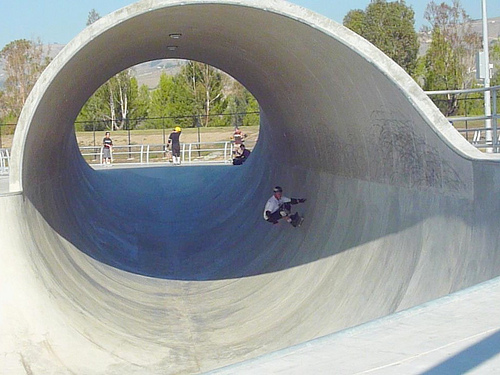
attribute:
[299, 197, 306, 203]
glove — black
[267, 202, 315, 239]
pant — black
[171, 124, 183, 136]
helmet — yellow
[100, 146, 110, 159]
short — gray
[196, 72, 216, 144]
tree — tall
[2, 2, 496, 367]
surface — gray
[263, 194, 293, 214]
shirt — white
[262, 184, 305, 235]
man — skating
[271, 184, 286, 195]
helmet — worn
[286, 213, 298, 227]
skateboard — gray